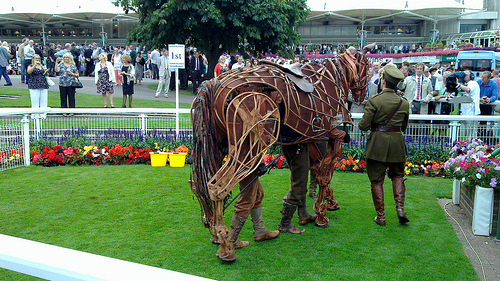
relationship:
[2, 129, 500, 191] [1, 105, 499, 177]
flowers beside fence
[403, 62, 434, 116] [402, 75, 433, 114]
man wears coat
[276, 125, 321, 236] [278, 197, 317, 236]
man wears boots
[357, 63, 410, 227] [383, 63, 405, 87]
man wears hat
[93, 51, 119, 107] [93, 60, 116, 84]
woman wears sweater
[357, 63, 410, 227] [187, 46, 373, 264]
man leads horse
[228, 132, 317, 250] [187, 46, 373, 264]
legs in costume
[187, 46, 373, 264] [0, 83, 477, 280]
horse in grass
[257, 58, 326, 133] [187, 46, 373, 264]
saddle on horse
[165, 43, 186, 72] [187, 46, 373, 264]
sign in front of horse